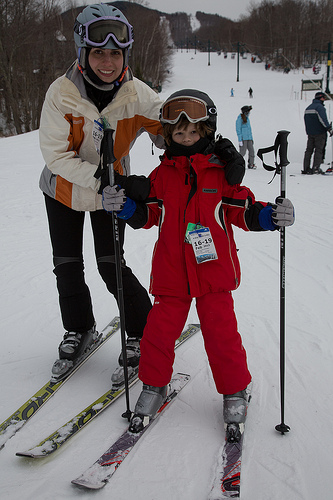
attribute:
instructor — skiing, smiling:
[40, 6, 165, 367]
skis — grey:
[73, 373, 255, 499]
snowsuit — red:
[133, 153, 254, 394]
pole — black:
[257, 131, 293, 435]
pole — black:
[102, 127, 136, 420]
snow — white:
[0, 127, 66, 425]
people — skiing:
[226, 85, 256, 101]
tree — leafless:
[1, 0, 17, 135]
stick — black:
[272, 127, 292, 435]